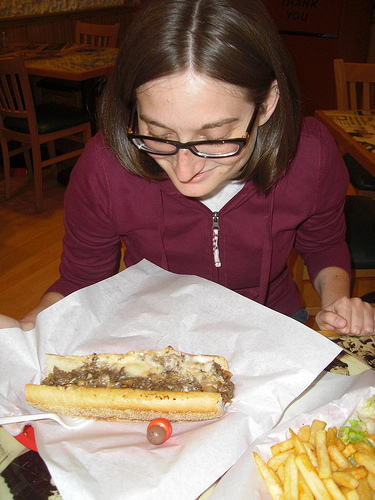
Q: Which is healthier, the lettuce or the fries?
A: The lettuce is healthier than the fries.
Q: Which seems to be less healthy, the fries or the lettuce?
A: The fries is less healthy than the lettuce.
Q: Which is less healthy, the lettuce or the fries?
A: The fries is less healthy than the lettuce.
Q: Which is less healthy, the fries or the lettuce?
A: The fries is less healthy than the lettuce.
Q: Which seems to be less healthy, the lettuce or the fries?
A: The fries is less healthy than the lettuce.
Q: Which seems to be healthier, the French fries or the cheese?
A: The cheese is healthier than the French fries.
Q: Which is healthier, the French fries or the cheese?
A: The cheese is healthier than the French fries.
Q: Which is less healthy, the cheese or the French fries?
A: The French fries is less healthy than the cheese.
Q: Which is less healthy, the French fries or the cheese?
A: The French fries is less healthy than the cheese.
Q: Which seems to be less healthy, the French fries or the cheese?
A: The French fries is less healthy than the cheese.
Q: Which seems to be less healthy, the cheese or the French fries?
A: The French fries is less healthy than the cheese.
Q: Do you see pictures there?
A: No, there are no pictures.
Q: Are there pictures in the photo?
A: No, there are no pictures.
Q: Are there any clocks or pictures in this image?
A: No, there are no pictures or clocks.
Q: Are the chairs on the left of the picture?
A: Yes, the chairs are on the left of the image.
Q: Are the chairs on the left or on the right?
A: The chairs are on the left of the image.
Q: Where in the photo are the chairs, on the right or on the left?
A: The chairs are on the left of the image.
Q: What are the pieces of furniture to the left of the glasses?
A: The pieces of furniture are chairs.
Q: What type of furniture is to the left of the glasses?
A: The pieces of furniture are chairs.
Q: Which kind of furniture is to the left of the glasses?
A: The pieces of furniture are chairs.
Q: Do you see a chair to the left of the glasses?
A: Yes, there are chairs to the left of the glasses.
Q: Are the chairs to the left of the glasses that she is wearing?
A: Yes, the chairs are to the left of the glasses.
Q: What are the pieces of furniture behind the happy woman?
A: The pieces of furniture are chairs.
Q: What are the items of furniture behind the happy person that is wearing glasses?
A: The pieces of furniture are chairs.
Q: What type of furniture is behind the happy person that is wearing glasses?
A: The pieces of furniture are chairs.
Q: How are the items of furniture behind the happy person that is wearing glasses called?
A: The pieces of furniture are chairs.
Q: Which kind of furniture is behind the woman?
A: The pieces of furniture are chairs.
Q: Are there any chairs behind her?
A: Yes, there are chairs behind the woman.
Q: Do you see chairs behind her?
A: Yes, there are chairs behind the woman.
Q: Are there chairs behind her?
A: Yes, there are chairs behind the woman.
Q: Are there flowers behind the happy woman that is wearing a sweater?
A: No, there are chairs behind the woman.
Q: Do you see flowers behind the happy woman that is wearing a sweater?
A: No, there are chairs behind the woman.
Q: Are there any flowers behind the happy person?
A: No, there are chairs behind the woman.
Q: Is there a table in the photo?
A: Yes, there is a table.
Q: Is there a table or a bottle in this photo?
A: Yes, there is a table.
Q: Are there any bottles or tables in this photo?
A: Yes, there is a table.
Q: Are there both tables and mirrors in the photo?
A: No, there is a table but no mirrors.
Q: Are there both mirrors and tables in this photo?
A: No, there is a table but no mirrors.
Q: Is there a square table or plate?
A: Yes, there is a square table.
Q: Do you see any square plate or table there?
A: Yes, there is a square table.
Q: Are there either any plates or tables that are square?
A: Yes, the table is square.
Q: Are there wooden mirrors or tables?
A: Yes, there is a wood table.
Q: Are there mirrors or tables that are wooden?
A: Yes, the table is wooden.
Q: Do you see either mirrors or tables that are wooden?
A: Yes, the table is wooden.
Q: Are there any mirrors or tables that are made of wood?
A: Yes, the table is made of wood.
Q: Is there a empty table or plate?
A: Yes, there is an empty table.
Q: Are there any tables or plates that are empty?
A: Yes, the table is empty.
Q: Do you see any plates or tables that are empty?
A: Yes, the table is empty.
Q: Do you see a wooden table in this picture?
A: Yes, there is a wood table.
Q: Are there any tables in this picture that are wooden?
A: Yes, there is a table that is wooden.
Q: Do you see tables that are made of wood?
A: Yes, there is a table that is made of wood.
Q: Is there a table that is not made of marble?
A: Yes, there is a table that is made of wood.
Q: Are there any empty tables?
A: Yes, there is an empty table.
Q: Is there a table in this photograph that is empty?
A: Yes, there is a table that is empty.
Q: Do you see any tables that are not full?
A: Yes, there is a empty table.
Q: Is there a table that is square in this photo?
A: Yes, there is a square table.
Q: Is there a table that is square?
A: Yes, there is a table that is square.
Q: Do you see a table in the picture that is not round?
A: Yes, there is a square table.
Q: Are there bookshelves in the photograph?
A: No, there are no bookshelves.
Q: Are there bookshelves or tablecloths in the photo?
A: No, there are no bookshelves or tablecloths.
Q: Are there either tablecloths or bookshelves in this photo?
A: No, there are no bookshelves or tablecloths.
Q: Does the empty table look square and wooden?
A: Yes, the table is square and wooden.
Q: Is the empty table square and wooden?
A: Yes, the table is square and wooden.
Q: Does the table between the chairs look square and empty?
A: Yes, the table is square and empty.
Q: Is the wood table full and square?
A: No, the table is square but empty.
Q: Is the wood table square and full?
A: No, the table is square but empty.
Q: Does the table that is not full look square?
A: Yes, the table is square.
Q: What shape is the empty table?
A: The table is square.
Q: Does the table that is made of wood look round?
A: No, the table is square.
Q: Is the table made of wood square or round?
A: The table is square.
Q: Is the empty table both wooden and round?
A: No, the table is wooden but square.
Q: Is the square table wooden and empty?
A: Yes, the table is wooden and empty.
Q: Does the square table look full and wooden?
A: No, the table is wooden but empty.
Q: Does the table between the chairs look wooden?
A: Yes, the table is wooden.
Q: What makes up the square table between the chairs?
A: The table is made of wood.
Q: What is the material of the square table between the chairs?
A: The table is made of wood.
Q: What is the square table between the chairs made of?
A: The table is made of wood.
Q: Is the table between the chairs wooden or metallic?
A: The table is wooden.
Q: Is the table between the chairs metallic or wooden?
A: The table is wooden.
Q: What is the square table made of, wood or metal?
A: The table is made of wood.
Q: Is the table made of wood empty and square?
A: Yes, the table is empty and square.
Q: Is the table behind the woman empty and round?
A: No, the table is empty but square.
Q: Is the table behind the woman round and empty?
A: No, the table is empty but square.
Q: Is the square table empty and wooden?
A: Yes, the table is empty and wooden.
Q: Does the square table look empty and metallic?
A: No, the table is empty but wooden.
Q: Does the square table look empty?
A: Yes, the table is empty.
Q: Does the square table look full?
A: No, the table is empty.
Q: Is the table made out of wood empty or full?
A: The table is empty.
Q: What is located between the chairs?
A: The table is between the chairs.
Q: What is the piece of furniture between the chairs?
A: The piece of furniture is a table.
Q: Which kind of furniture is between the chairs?
A: The piece of furniture is a table.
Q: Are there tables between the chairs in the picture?
A: Yes, there is a table between the chairs.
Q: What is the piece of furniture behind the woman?
A: The piece of furniture is a table.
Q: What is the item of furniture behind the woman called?
A: The piece of furniture is a table.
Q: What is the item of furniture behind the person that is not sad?
A: The piece of furniture is a table.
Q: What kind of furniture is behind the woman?
A: The piece of furniture is a table.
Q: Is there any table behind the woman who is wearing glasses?
A: Yes, there is a table behind the woman.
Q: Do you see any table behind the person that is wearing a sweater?
A: Yes, there is a table behind the woman.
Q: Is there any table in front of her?
A: No, the table is behind the woman.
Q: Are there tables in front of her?
A: No, the table is behind the woman.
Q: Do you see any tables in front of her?
A: No, the table is behind the woman.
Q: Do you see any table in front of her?
A: No, the table is behind the woman.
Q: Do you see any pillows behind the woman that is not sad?
A: No, there is a table behind the woman.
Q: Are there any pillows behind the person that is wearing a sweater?
A: No, there is a table behind the woman.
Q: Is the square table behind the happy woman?
A: Yes, the table is behind the woman.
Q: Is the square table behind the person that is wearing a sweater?
A: Yes, the table is behind the woman.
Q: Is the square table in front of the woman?
A: No, the table is behind the woman.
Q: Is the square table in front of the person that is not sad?
A: No, the table is behind the woman.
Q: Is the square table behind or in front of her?
A: The table is behind the woman.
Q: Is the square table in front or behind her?
A: The table is behind the woman.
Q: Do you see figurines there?
A: No, there are no figurines.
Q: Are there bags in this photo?
A: No, there are no bags.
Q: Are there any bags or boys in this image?
A: No, there are no bags or boys.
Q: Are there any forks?
A: Yes, there is a fork.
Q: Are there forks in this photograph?
A: Yes, there is a fork.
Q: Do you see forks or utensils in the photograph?
A: Yes, there is a fork.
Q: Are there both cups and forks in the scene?
A: No, there is a fork but no cups.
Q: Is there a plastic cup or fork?
A: Yes, there is a plastic fork.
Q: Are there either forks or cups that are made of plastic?
A: Yes, the fork is made of plastic.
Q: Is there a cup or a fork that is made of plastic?
A: Yes, the fork is made of plastic.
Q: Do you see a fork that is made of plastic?
A: Yes, there is a fork that is made of plastic.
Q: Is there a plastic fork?
A: Yes, there is a fork that is made of plastic.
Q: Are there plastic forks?
A: Yes, there is a fork that is made of plastic.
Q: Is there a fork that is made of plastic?
A: Yes, there is a fork that is made of plastic.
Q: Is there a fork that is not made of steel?
A: Yes, there is a fork that is made of plastic.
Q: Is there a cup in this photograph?
A: No, there are no cups.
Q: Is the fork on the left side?
A: Yes, the fork is on the left of the image.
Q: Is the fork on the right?
A: No, the fork is on the left of the image.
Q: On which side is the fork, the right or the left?
A: The fork is on the left of the image.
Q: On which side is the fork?
A: The fork is on the left of the image.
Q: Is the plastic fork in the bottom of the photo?
A: Yes, the fork is in the bottom of the image.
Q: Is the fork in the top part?
A: No, the fork is in the bottom of the image.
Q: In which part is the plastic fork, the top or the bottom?
A: The fork is in the bottom of the image.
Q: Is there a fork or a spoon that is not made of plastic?
A: No, there is a fork but it is made of plastic.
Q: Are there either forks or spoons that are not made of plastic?
A: No, there is a fork but it is made of plastic.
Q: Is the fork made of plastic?
A: Yes, the fork is made of plastic.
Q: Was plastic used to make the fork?
A: Yes, the fork is made of plastic.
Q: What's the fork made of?
A: The fork is made of plastic.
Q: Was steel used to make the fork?
A: No, the fork is made of plastic.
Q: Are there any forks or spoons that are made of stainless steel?
A: No, there is a fork but it is made of plastic.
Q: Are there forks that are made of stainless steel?
A: No, there is a fork but it is made of plastic.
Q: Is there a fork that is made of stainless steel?
A: No, there is a fork but it is made of plastic.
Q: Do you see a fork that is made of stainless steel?
A: No, there is a fork but it is made of plastic.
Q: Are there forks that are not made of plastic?
A: No, there is a fork but it is made of plastic.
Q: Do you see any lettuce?
A: Yes, there is lettuce.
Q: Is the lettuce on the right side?
A: Yes, the lettuce is on the right of the image.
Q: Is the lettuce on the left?
A: No, the lettuce is on the right of the image.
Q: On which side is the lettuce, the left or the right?
A: The lettuce is on the right of the image.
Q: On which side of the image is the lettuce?
A: The lettuce is on the right of the image.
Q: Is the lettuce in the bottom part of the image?
A: Yes, the lettuce is in the bottom of the image.